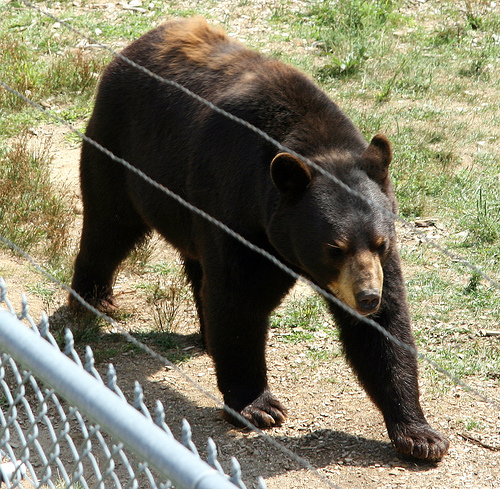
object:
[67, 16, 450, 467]
bear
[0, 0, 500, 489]
ground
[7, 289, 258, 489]
fence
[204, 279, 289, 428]
legs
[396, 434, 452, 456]
claws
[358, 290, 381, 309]
nose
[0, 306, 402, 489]
shadow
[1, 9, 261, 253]
fence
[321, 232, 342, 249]
eyes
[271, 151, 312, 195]
ears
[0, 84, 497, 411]
wires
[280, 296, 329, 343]
grass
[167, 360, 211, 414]
dirt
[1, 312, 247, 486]
pipe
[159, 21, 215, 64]
fur